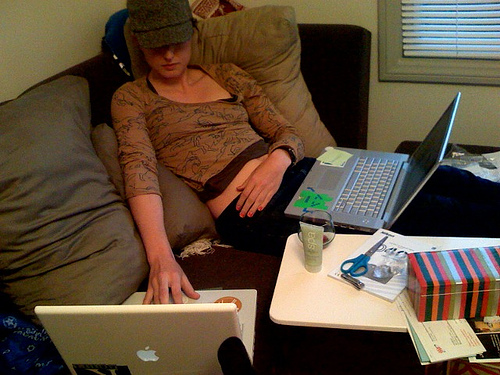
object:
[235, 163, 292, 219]
hand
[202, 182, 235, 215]
stomach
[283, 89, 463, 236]
table laptop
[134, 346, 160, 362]
logo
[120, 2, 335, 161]
pillow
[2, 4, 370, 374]
sofa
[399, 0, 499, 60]
blinds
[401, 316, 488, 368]
papers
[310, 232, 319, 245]
liquid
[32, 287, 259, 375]
laptop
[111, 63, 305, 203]
shirt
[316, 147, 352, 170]
stickie note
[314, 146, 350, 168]
yellow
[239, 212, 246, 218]
nails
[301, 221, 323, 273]
bottle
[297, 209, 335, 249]
glass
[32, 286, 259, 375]
computer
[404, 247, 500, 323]
striped box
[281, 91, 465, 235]
lap top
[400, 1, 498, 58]
window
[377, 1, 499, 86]
frame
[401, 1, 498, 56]
venetian blind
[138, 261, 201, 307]
hand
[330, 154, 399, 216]
keyboard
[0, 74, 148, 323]
pillow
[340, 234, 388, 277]
scissors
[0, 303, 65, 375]
cloth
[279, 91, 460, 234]
laptop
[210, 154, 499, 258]
girl's lap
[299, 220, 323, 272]
lotion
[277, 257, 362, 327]
table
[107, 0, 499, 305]
girl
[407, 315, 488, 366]
documents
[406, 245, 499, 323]
box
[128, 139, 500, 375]
table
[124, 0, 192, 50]
cap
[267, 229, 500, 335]
table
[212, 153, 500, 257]
pants